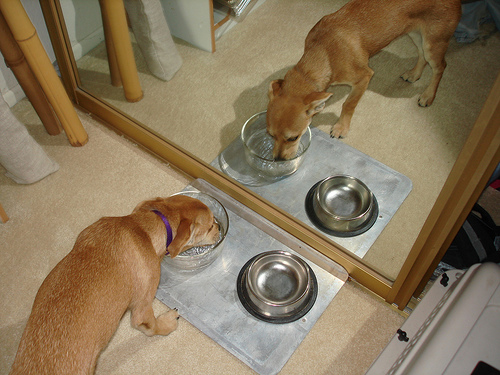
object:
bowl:
[236, 252, 317, 325]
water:
[259, 266, 294, 291]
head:
[135, 197, 223, 249]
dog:
[12, 196, 221, 372]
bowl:
[158, 191, 229, 269]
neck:
[127, 205, 181, 264]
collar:
[149, 205, 176, 258]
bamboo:
[3, 1, 91, 146]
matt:
[162, 269, 238, 319]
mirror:
[75, 1, 499, 150]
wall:
[0, 2, 57, 109]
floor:
[1, 137, 149, 205]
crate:
[386, 280, 500, 374]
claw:
[156, 307, 183, 330]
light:
[219, 136, 290, 188]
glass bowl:
[242, 111, 312, 177]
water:
[171, 243, 225, 271]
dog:
[264, 2, 461, 163]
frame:
[386, 1, 499, 313]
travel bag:
[436, 201, 498, 268]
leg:
[331, 66, 375, 140]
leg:
[399, 26, 428, 84]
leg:
[416, 37, 453, 110]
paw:
[329, 120, 352, 139]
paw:
[416, 90, 438, 109]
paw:
[399, 65, 422, 87]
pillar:
[103, 2, 145, 101]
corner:
[59, 1, 148, 97]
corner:
[6, 1, 136, 199]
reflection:
[163, 7, 466, 234]